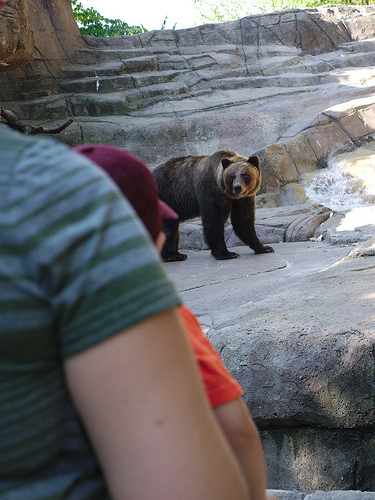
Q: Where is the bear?
A: On a rock.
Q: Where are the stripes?
A: On green shirt.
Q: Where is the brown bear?
A: In a zoo.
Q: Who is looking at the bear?
A: A boy and a woman.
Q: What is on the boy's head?
A: A maroon hat.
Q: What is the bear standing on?
A: Rock.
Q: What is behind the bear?
A: More rock.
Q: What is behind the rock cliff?
A: Trees and sunlight.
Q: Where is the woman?
A: Behind the boy.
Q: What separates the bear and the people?
A: Glass.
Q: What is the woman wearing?
A: A gray shirt.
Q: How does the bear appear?
A: Big and brown.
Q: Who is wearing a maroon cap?
A: A kid.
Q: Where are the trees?
A: Behind rocks.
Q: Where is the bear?
A: On rocks.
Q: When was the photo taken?
A: Sunny day.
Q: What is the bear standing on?
A: Rocks.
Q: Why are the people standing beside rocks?
A: Watching bear.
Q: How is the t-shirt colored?
A: Green with stripes.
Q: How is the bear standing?
A: On four legs.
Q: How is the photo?
A: Clear.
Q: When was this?
A: Daytime.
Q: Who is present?
A: People.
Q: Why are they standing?
A: To see.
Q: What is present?
A: An animal.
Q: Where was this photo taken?
A: In a zoo.